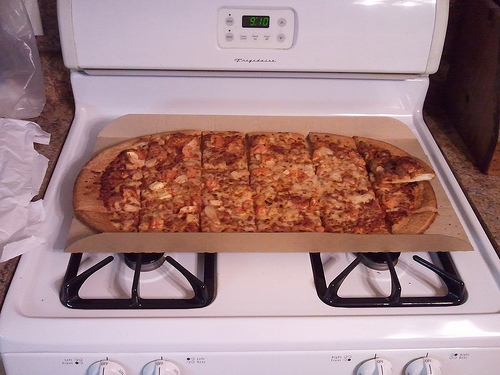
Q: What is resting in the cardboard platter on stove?
A: A baked pizza.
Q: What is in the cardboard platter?
A: Baked pizza.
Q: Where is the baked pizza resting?
A: In a cradboard platter on a stove.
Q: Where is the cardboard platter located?
A: On a stove.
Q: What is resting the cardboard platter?
A: A baked pizza.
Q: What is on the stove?
A: A pizza.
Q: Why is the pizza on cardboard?
A: The pizza was baked in a store and was picked up or delivered.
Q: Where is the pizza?
A: In the kitchen.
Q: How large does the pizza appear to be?
A: The pizza is large, as it is as wide as the stove.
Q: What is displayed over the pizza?
A: A stove clock.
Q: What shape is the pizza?
A: Oval.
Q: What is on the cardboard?
A: Pizza.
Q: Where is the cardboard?
A: On the range.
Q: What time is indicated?
A: 9:10.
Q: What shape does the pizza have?
A: Oval.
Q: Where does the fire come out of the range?
A: The burners.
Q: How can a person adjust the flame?
A: With the knobs.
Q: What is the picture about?
A: Pizza.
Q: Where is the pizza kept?
A: On the gas stove.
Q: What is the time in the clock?
A: 9:10.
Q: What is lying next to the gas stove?
A: A white paper.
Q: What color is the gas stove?
A: White.